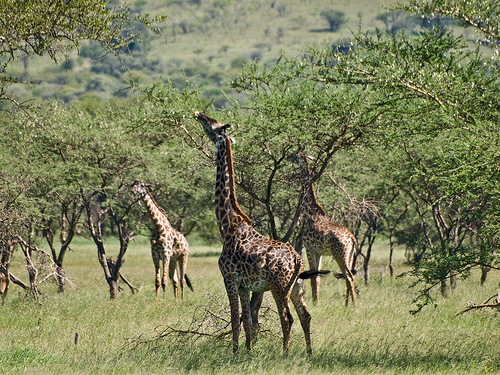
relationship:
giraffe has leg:
[191, 109, 312, 359] [215, 258, 242, 356]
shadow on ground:
[178, 332, 481, 372] [1, 226, 483, 370]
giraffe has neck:
[177, 106, 353, 372] [209, 141, 249, 219]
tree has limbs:
[96, 35, 498, 301] [306, 125, 358, 174]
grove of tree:
[14, 9, 461, 239] [96, 35, 498, 301]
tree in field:
[96, 35, 498, 301] [8, 230, 484, 363]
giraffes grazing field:
[116, 127, 414, 307] [8, 230, 484, 363]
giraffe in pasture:
[191, 109, 312, 359] [10, 220, 482, 353]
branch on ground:
[154, 311, 278, 344] [344, 310, 496, 358]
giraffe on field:
[130, 179, 195, 302] [8, 230, 484, 363]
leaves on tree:
[0, 0, 168, 60] [2, 2, 172, 302]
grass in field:
[5, 262, 496, 371] [2, 235, 497, 373]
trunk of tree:
[0, 237, 17, 294] [0, 2, 170, 97]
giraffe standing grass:
[130, 179, 195, 302] [331, 299, 498, 354]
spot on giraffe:
[230, 226, 250, 242] [165, 105, 330, 364]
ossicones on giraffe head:
[220, 111, 235, 141] [193, 110, 232, 145]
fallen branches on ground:
[141, 299, 284, 344] [1, 226, 483, 370]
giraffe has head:
[134, 162, 187, 250] [192, 98, 244, 150]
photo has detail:
[7, 10, 495, 372] [74, 78, 434, 217]